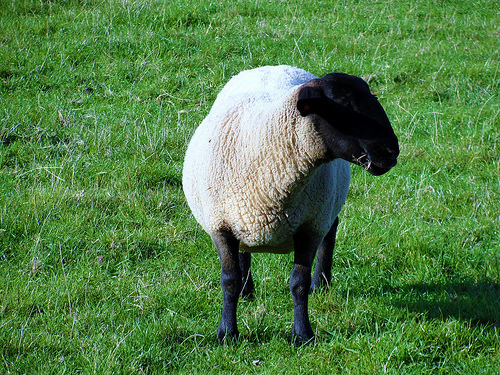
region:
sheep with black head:
[172, 51, 411, 348]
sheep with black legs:
[173, 47, 413, 352]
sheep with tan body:
[175, 43, 412, 348]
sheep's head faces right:
[176, 53, 405, 344]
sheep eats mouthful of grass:
[192, 51, 422, 209]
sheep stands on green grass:
[160, 45, 418, 356]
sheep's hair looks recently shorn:
[0, 5, 495, 366]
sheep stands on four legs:
[162, 41, 415, 357]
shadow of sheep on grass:
[125, 150, 494, 357]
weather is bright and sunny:
[3, 0, 499, 370]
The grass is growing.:
[19, 81, 177, 318]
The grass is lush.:
[33, 72, 144, 329]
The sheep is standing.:
[162, 46, 397, 350]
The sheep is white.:
[177, 43, 428, 353]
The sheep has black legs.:
[179, 206, 393, 364]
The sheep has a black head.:
[275, 61, 423, 198]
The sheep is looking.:
[167, 48, 409, 369]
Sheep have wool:
[166, 35, 417, 370]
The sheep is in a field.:
[36, 21, 488, 293]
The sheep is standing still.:
[35, 22, 469, 359]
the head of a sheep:
[296, 62, 404, 183]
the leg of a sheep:
[287, 247, 317, 344]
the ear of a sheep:
[282, 80, 327, 119]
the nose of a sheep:
[380, 137, 407, 157]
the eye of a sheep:
[338, 96, 359, 117]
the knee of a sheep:
[221, 275, 242, 297]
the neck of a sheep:
[249, 86, 329, 188]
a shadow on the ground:
[304, 267, 499, 357]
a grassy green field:
[1, 0, 497, 372]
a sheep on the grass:
[173, 50, 408, 363]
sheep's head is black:
[290, 43, 406, 190]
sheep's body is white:
[170, 40, 341, 222]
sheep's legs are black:
[175, 194, 378, 341]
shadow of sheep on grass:
[326, 248, 492, 335]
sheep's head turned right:
[283, 60, 433, 190]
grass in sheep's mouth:
[340, 139, 418, 199]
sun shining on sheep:
[1, 1, 498, 353]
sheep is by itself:
[49, 3, 495, 373]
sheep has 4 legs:
[193, 226, 373, 346]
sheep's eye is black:
[322, 85, 392, 130]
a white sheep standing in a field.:
[177, 63, 410, 338]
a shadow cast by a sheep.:
[382, 251, 497, 341]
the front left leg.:
[277, 240, 324, 349]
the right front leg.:
[193, 216, 257, 343]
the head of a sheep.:
[284, 47, 425, 188]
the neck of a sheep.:
[258, 78, 316, 209]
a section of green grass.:
[52, 76, 134, 210]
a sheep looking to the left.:
[171, 47, 413, 347]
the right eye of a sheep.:
[347, 98, 371, 138]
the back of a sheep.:
[211, 58, 314, 130]